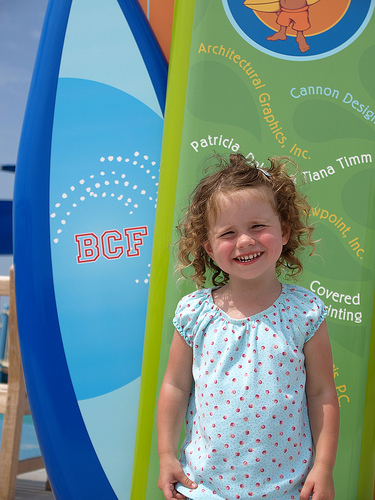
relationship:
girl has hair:
[157, 149, 341, 499] [170, 147, 325, 294]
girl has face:
[157, 149, 341, 499] [208, 186, 284, 280]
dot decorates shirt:
[222, 325, 227, 331] [172, 282, 330, 499]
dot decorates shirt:
[304, 320, 311, 328] [172, 282, 330, 499]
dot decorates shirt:
[244, 429, 250, 435] [172, 282, 330, 499]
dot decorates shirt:
[209, 464, 217, 472] [172, 282, 330, 499]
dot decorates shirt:
[278, 474, 284, 480] [172, 282, 330, 499]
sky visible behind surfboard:
[2, 1, 52, 165] [13, 1, 168, 498]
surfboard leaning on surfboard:
[13, 1, 168, 498] [127, 1, 374, 499]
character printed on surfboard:
[242, 1, 352, 54] [127, 1, 374, 499]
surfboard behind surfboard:
[139, 1, 173, 67] [13, 1, 168, 498]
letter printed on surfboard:
[76, 234, 101, 264] [13, 1, 168, 498]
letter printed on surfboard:
[102, 230, 125, 260] [13, 1, 168, 498]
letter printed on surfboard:
[124, 227, 148, 259] [13, 1, 168, 498]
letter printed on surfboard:
[290, 88, 299, 100] [127, 1, 374, 499]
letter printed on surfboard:
[190, 141, 201, 156] [127, 1, 374, 499]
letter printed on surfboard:
[197, 41, 207, 56] [127, 1, 374, 499]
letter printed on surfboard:
[309, 279, 321, 293] [127, 1, 374, 499]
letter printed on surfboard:
[335, 156, 346, 173] [127, 1, 374, 499]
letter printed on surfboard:
[258, 92, 272, 104] [127, 1, 374, 499]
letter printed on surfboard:
[341, 92, 353, 104] [127, 1, 374, 499]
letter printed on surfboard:
[348, 237, 362, 247] [127, 1, 374, 499]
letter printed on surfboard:
[287, 143, 299, 157] [127, 1, 374, 499]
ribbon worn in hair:
[256, 166, 271, 180] [170, 147, 325, 294]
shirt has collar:
[172, 282, 330, 499] [210, 283, 286, 325]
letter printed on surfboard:
[72, 228, 101, 266] [13, 1, 168, 498]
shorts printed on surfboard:
[276, 5, 312, 32] [127, 1, 374, 499]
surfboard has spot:
[13, 1, 168, 498] [107, 155, 116, 163]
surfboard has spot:
[13, 1, 168, 498] [140, 190, 145, 197]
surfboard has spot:
[13, 1, 168, 498] [50, 212, 58, 219]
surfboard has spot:
[13, 1, 168, 498] [70, 186, 77, 193]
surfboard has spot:
[13, 1, 168, 498] [133, 151, 139, 156]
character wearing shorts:
[242, 1, 352, 54] [276, 5, 312, 32]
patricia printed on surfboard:
[191, 135, 240, 156] [127, 1, 374, 499]